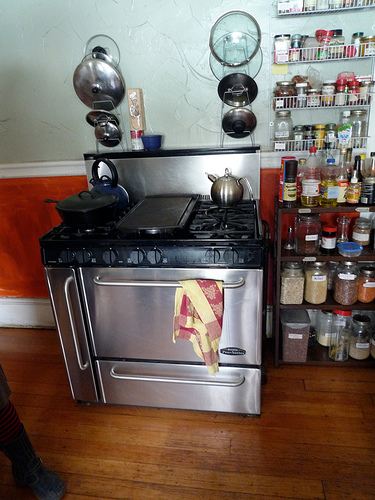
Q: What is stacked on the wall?
A: Pot and pan lids.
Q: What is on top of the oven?
A: A stove.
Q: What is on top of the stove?
A: Pans and pots.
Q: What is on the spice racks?
A: Spices.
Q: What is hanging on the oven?
A: A towel.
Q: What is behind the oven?
A: A wall.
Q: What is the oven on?
A: A floor.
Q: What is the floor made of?
A: Wood.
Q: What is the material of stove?
A: Steel.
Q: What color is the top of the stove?
A: Black.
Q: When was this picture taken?
A: Daytime.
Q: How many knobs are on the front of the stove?
A: 7.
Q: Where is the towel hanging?
A: Front of stove.